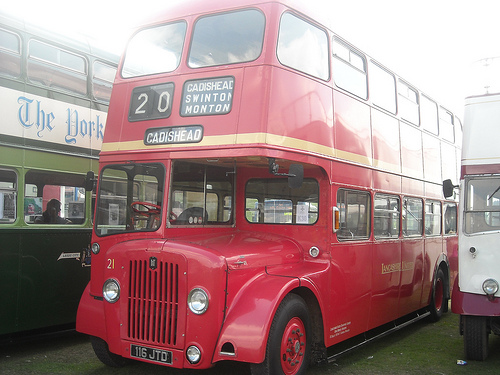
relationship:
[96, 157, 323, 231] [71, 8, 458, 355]
winshield of a bus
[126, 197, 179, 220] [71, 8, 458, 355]
wheel of a bus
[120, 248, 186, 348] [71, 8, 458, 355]
grill of a bus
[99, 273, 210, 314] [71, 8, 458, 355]
headlights of a bus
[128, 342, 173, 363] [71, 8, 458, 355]
license plate of a bus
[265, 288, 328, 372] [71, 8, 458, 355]
wheel of a bus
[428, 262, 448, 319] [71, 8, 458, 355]
wheel of a bus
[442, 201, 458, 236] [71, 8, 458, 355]
window of a bus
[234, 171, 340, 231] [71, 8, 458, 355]
window attached to bus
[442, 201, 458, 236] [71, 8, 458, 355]
window attached to bus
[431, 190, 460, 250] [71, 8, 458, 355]
window attached to bus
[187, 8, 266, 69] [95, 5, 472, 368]
window attached to bus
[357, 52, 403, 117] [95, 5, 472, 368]
window attached to bus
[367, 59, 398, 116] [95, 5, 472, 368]
window attached to bus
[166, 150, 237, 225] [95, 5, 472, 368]
window attached to bus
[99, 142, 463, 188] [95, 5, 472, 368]
trim attached to bus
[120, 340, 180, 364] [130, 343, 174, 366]
letters are printed on license plate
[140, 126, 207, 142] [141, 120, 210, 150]
letters are printed on sign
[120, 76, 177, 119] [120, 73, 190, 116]
numerals are printed on sign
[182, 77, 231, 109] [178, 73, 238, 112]
letters are printed on sign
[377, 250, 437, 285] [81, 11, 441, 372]
lettering printed on bus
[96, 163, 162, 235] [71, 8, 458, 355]
window of bus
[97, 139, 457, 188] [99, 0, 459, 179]
trim at bottom of level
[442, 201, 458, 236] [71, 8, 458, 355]
window of bus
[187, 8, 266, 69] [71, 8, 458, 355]
window of bus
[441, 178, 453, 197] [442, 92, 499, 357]
mirror of bus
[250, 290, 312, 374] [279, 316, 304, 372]
wheel on rim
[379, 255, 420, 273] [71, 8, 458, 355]
writing on bus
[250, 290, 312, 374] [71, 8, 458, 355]
wheel of bus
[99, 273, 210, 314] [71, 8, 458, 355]
headlights of bus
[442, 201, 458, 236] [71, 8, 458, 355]
window on side of bus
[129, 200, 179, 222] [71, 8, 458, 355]
wheel in bus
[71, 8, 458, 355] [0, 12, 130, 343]
bus between bus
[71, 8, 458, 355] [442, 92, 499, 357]
bus between bus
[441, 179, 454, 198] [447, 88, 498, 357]
mirror on bus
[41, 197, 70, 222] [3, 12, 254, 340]
person sitting on bus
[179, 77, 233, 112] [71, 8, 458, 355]
destination of bus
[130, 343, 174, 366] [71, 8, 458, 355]
license plate on bus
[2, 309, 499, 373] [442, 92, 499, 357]
ground beneath bus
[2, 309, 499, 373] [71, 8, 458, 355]
ground beneath bus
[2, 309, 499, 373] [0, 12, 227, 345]
ground beneath bus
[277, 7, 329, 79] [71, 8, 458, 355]
window on bus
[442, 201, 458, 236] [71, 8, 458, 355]
window on bus